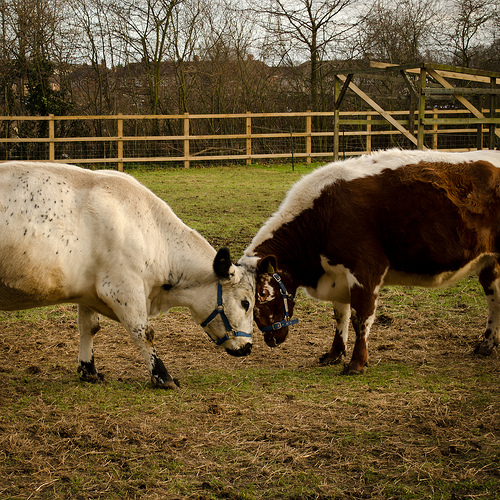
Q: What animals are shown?
A: Cows.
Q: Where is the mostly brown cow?
A: On the right.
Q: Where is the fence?
A: Behind the cows.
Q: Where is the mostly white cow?
A: On the left.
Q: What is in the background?
A: Bald trees that are missing their leaves.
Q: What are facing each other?
A: A pair of cows.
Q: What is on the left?
A: A large white cow.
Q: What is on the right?
A: A large brown and white cow.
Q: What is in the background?
A: Wooden fence.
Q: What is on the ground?
A: Green and dried grass.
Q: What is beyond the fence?
A: Group of trees.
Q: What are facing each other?
A: Two cows.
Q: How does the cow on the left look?
A: The cow is brown and white.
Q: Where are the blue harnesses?
A: On the head.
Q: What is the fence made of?
A: Wood.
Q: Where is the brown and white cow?
A: Right side.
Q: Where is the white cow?
A: Left side.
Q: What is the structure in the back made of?
A: Wood.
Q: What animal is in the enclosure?
A: Cows.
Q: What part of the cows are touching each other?
A: Foreheads.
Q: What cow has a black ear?
A: White cow.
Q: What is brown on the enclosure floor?
A: Hay.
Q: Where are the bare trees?
A: Other side of the fence.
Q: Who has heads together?
A: Two cows.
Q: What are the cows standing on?
A: Grass.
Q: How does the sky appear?
A: Overcast.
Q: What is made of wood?
A: The fence.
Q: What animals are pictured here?
A: Cows.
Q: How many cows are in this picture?
A: 2.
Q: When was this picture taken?
A: Daytime.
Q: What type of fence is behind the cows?
A: A wooden one.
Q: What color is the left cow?
A: White.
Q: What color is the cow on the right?
A: Brown and white.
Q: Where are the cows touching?
A: On their heads.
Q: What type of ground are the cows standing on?
A: Grass.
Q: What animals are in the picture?
A: Cows.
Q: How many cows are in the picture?
A: Two.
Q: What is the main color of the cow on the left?
A: White.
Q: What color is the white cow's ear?
A: Black.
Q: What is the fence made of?
A: Wood.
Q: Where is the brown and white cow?
A: On the right.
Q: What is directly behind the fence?
A: Trees.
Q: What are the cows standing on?
A: The grass.